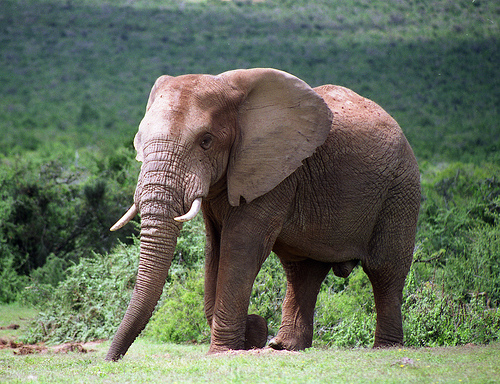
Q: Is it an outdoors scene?
A: Yes, it is outdoors.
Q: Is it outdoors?
A: Yes, it is outdoors.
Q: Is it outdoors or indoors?
A: It is outdoors.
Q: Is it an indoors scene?
A: No, it is outdoors.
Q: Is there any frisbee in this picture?
A: No, there are no frisbees.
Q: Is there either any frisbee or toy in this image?
A: No, there are no frisbees or toys.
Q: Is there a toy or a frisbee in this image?
A: No, there are no frisbees or toys.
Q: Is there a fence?
A: No, there are no fences.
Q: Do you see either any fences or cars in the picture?
A: No, there are no fences or cars.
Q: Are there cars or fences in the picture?
A: No, there are no fences or cars.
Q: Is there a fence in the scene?
A: No, there are no fences.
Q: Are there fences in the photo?
A: No, there are no fences.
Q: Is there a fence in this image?
A: No, there are no fences.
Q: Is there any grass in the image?
A: Yes, there is grass.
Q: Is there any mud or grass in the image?
A: Yes, there is grass.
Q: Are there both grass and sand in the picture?
A: No, there is grass but no sand.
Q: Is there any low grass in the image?
A: Yes, there is low grass.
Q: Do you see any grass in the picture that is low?
A: Yes, there is low grass.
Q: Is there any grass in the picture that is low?
A: Yes, there is grass that is low.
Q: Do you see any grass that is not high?
A: Yes, there is low grass.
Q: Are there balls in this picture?
A: No, there are no balls.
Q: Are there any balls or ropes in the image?
A: No, there are no balls or ropes.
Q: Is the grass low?
A: Yes, the grass is low.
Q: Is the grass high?
A: No, the grass is low.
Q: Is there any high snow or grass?
A: No, there is grass but it is low.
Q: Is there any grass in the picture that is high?
A: No, there is grass but it is low.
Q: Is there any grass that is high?
A: No, there is grass but it is low.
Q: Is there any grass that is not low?
A: No, there is grass but it is low.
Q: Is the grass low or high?
A: The grass is low.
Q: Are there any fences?
A: No, there are no fences.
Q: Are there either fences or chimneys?
A: No, there are no fences or chimneys.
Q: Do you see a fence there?
A: No, there are no fences.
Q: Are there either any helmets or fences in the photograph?
A: No, there are no fences or helmets.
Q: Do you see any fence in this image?
A: No, there are no fences.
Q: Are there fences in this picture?
A: No, there are no fences.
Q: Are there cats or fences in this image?
A: No, there are no fences or cats.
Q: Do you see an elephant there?
A: Yes, there is an elephant.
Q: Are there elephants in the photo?
A: Yes, there is an elephant.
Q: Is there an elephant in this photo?
A: Yes, there is an elephant.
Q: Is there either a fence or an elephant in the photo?
A: Yes, there is an elephant.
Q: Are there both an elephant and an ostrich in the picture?
A: No, there is an elephant but no ostriches.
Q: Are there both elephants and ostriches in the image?
A: No, there is an elephant but no ostriches.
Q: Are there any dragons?
A: No, there are no dragons.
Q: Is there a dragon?
A: No, there are no dragons.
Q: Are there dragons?
A: No, there are no dragons.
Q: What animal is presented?
A: The animal is an elephant.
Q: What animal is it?
A: The animal is an elephant.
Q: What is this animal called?
A: This is an elephant.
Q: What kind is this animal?
A: This is an elephant.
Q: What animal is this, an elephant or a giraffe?
A: This is an elephant.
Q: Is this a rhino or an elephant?
A: This is an elephant.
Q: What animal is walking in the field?
A: The elephant is walking in the field.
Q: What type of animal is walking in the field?
A: The animal is an elephant.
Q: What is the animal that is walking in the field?
A: The animal is an elephant.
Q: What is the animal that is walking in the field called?
A: The animal is an elephant.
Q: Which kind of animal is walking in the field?
A: The animal is an elephant.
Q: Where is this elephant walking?
A: The elephant is walking in the field.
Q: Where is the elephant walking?
A: The elephant is walking in the field.